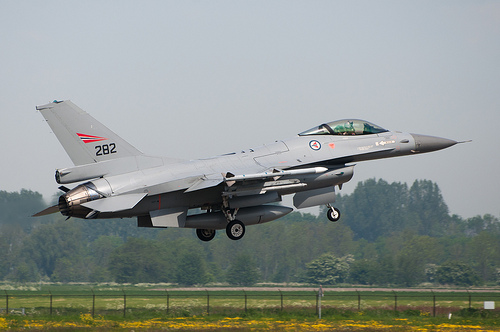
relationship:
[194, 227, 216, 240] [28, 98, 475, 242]
wheel on airplane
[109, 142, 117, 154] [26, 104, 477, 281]
number on jet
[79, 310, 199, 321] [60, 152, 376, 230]
field near airplane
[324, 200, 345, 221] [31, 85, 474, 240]
wheel on plane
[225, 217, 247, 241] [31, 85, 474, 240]
wheel on plane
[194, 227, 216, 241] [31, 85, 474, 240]
wheel on plane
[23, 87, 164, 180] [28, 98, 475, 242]
wing on airplane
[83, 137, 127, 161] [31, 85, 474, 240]
number on plane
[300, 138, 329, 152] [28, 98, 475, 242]
decal on airplane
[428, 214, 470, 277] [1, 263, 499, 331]
trees near field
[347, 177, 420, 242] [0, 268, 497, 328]
trees near field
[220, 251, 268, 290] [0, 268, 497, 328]
tree near field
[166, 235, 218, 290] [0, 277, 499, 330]
tree near field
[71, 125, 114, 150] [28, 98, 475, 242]
logo on airplane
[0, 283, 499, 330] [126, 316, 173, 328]
grass has patch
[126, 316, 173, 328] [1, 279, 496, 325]
patch in field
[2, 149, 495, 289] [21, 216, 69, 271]
forest has tree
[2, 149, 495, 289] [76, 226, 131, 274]
forest has tree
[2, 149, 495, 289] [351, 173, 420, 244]
forest has tree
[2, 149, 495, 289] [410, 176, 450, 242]
forest has tree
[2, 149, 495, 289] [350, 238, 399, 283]
forest has tree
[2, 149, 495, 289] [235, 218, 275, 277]
forest has tree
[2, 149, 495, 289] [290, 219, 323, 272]
forest has tree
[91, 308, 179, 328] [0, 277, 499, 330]
flowers are in field field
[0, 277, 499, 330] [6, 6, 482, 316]
field in airport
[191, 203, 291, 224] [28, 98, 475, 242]
missiles are on airplane